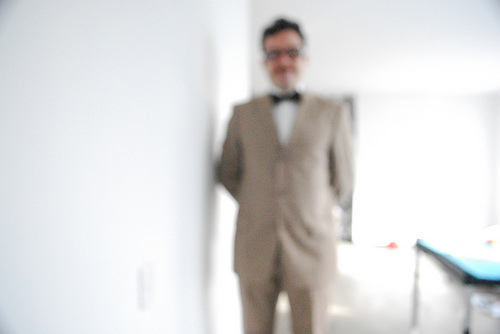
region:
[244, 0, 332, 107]
the head of a man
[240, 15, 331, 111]
a man wearing glasses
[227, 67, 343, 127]
a man wearing a bow tie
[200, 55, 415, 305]
a man wearing a suit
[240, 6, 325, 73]
the hair of a man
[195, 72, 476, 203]
a man wearing a brown shirt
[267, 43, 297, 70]
the nose of a shirt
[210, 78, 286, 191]
the arm of a man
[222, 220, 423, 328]
a man wearing pants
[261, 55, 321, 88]
the mouth of a man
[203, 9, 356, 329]
a man standing by a wall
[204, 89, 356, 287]
the coat is beige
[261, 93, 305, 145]
his shirt is white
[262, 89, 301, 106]
he is wearing a black bowtie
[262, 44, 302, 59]
his glasses have dark frames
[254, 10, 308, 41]
his hair is dark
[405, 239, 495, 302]
a blue cloth on the side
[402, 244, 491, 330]
table legs under the table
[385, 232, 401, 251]
a random red speck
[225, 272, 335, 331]
his legs are beige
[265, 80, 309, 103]
man is wearing a bow tie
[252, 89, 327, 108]
man is wearing a bow tie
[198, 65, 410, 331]
the suit is light brown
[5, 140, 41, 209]
Small section of white wall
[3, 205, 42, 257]
Small section of white wall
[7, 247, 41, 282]
Small section of white wall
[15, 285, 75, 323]
Small section of white wall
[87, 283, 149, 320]
Small section of white wall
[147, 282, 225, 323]
Small section of white wall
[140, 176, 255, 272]
Small section of white wall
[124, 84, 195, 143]
Small section of white wall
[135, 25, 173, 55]
Small section of white wall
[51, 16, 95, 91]
Small section of white wall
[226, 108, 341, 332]
the suit is brown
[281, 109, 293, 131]
the shirt is white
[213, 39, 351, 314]
the man has glasses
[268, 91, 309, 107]
the bow te is black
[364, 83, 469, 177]
the background is blurred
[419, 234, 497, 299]
the table is blue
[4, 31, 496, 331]
the scene is indoors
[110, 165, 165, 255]
the wall made of concrete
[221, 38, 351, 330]
the man is posing for a picture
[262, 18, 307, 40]
the hair is black